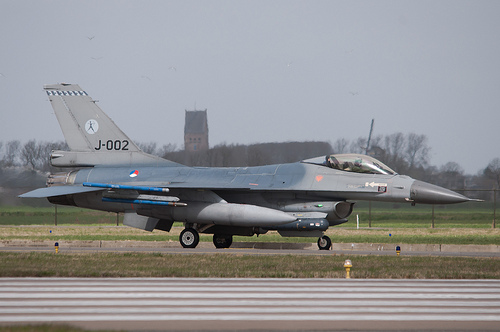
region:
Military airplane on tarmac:
[34, 76, 481, 276]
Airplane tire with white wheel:
[172, 223, 204, 251]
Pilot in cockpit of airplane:
[340, 150, 372, 177]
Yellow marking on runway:
[331, 249, 371, 290]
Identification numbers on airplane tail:
[86, 138, 136, 155]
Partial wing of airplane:
[6, 175, 128, 201]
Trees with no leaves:
[335, 125, 448, 176]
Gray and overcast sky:
[106, 16, 423, 91]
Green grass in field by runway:
[1, 190, 124, 230]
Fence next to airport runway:
[2, 198, 134, 230]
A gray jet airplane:
[26, 75, 481, 250]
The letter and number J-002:
[90, 130, 130, 150]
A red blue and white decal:
[120, 160, 146, 185]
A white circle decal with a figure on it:
[75, 115, 105, 135]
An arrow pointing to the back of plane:
[358, 176, 395, 198]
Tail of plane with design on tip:
[35, 70, 140, 145]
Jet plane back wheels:
[175, 220, 235, 240]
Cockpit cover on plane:
[300, 145, 395, 175]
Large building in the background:
[175, 100, 330, 150]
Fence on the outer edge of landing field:
[476, 180, 496, 225]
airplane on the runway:
[16, 63, 498, 275]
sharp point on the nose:
[444, 184, 491, 210]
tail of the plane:
[42, 71, 150, 156]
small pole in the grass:
[47, 239, 64, 256]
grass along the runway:
[4, 238, 486, 278]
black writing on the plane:
[93, 136, 133, 153]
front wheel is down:
[315, 228, 332, 253]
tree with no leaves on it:
[0, 136, 56, 168]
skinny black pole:
[364, 198, 376, 228]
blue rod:
[79, 175, 175, 196]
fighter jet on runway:
[19, 50, 464, 275]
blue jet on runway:
[24, 61, 467, 274]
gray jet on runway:
[21, 62, 445, 298]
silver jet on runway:
[30, 61, 484, 299]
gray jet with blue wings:
[28, 79, 455, 274]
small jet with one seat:
[282, 124, 469, 261]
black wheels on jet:
[169, 218, 360, 265]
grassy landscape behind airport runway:
[27, 80, 464, 282]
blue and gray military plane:
[18, 68, 478, 297]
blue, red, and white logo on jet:
[114, 167, 171, 190]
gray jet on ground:
[16, 72, 476, 250]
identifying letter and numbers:
[91, 131, 128, 151]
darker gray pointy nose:
[400, 171, 485, 202]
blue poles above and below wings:
[82, 177, 187, 202]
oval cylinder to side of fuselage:
[131, 201, 297, 221]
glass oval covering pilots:
[300, 146, 397, 176]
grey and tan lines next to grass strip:
[10, 246, 495, 326]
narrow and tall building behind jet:
[180, 100, 210, 167]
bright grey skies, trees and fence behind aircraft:
[335, 91, 470, 146]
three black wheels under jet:
[170, 220, 335, 250]